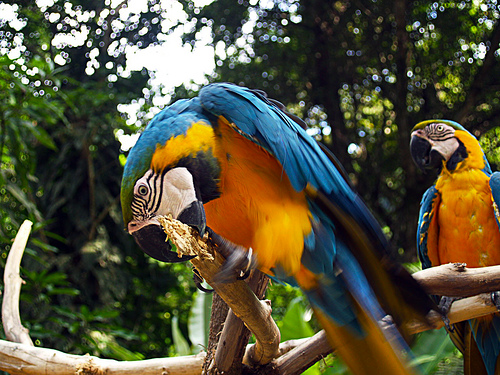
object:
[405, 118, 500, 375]
bird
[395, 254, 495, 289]
branch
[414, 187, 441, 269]
wing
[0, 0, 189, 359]
leaves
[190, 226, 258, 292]
claw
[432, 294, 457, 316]
claws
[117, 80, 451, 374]
bird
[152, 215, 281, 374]
branch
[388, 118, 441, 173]
ground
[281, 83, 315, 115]
leaves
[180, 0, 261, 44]
leaves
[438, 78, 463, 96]
leaves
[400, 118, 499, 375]
parrot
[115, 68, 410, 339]
parrot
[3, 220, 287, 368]
branch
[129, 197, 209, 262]
beak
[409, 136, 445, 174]
beak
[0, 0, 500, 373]
tree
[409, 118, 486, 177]
head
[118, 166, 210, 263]
head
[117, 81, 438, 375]
parrots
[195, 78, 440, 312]
wing